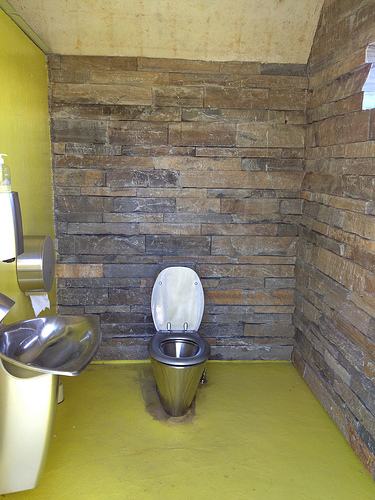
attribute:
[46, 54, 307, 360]
wall — bricks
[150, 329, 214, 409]
toilet — silver metal, bathroom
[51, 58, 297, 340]
wall — stone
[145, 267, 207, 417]
toilet — metal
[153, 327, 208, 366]
seat — metal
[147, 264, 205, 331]
lid — lifted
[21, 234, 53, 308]
toilet dispenser — metal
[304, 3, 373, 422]
wall — stone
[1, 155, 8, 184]
plastic bottle — clear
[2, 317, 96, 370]
sink — silver